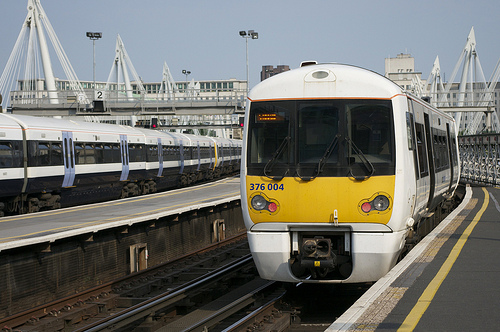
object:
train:
[239, 61, 462, 281]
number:
[250, 183, 285, 191]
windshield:
[249, 99, 396, 176]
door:
[61, 132, 75, 188]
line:
[394, 187, 490, 332]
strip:
[244, 176, 396, 228]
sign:
[256, 112, 287, 124]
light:
[373, 195, 390, 211]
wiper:
[313, 133, 343, 176]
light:
[239, 30, 260, 40]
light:
[86, 32, 103, 83]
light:
[152, 118, 158, 129]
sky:
[0, 0, 500, 83]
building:
[7, 78, 249, 118]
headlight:
[361, 203, 372, 214]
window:
[298, 101, 340, 165]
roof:
[0, 114, 243, 148]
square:
[95, 91, 106, 100]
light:
[239, 117, 245, 127]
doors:
[119, 134, 130, 181]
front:
[239, 175, 403, 282]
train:
[0, 113, 247, 213]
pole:
[244, 39, 248, 91]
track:
[83, 249, 293, 332]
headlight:
[251, 195, 277, 213]